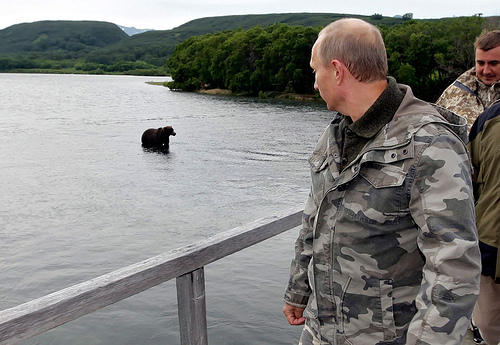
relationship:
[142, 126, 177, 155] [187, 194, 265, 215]
bear soaking wet in water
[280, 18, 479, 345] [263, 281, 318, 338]
man has hand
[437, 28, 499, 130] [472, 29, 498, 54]
man has brown hair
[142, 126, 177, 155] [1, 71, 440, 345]
bear in water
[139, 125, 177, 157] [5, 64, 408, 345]
bear in water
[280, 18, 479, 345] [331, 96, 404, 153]
man wearing shirt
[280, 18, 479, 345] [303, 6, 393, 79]
man has gray hair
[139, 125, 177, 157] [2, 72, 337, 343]
bear in water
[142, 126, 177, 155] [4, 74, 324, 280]
bear in water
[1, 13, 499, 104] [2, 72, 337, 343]
green trees by water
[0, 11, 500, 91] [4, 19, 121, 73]
hills of trees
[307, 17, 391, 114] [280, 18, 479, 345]
head turned man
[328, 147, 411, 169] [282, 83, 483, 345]
buttons on coat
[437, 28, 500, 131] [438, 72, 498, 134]
man wearing coat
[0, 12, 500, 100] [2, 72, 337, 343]
green trees by water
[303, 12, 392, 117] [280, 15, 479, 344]
head of a man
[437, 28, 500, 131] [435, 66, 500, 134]
man wearing coat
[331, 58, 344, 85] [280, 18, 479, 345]
ear of a man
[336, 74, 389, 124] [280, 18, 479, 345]
neck of a man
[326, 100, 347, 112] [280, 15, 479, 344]
chin of a man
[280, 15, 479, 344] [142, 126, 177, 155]
man watching bear